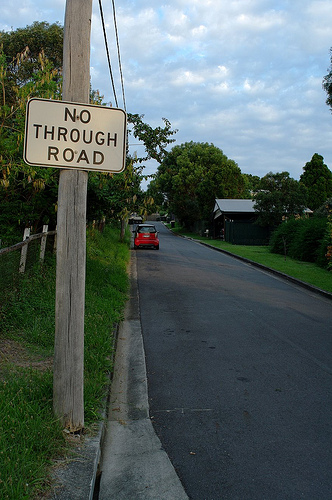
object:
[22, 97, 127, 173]
sign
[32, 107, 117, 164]
wording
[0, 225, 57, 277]
fence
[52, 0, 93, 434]
pole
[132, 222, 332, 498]
street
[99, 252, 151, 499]
curb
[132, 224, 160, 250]
car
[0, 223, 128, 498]
grass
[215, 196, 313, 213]
roof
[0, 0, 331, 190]
sky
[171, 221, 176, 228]
trash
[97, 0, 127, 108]
wire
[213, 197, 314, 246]
building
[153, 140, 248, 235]
tree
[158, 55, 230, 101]
cloud